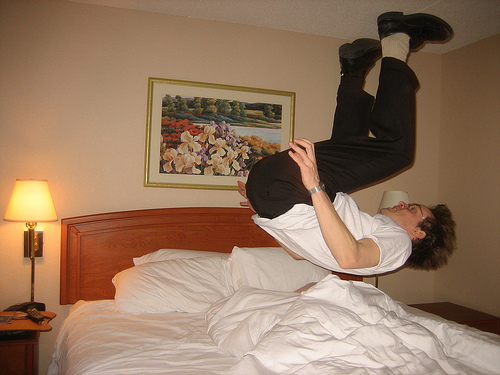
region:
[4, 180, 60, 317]
lamp on end table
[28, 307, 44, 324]
remote control on table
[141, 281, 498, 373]
white comforter on bed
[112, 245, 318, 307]
pillows laying on bed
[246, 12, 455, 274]
man jumping on bed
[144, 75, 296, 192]
picture hanging on wall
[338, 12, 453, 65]
black leather dress shoes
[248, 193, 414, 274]
white cotton tee shirt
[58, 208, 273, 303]
brown wood head board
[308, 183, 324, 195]
silver watch on wrist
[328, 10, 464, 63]
His shoes are black.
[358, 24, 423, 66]
His sock is tan.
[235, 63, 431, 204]
The pants are black.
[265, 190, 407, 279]
The shirt is white.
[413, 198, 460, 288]
His hair is brown.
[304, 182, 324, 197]
His watch is silver.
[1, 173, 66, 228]
The light is on.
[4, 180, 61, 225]
The lights is orange.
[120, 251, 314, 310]
The pillows are white.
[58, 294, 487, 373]
The comforter is white.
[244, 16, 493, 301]
Man flipping on a bed.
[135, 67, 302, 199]
Floral picture on the wall.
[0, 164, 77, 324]
Wall mounted light fixture.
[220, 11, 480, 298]
A man wearing a white shirt and black pants.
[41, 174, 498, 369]
An unmade bed.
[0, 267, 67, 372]
A cluttered nightstand.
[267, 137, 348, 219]
A silver watch.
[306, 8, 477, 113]
Black shoes and tan socks.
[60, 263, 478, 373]
White sheets and pillowcases.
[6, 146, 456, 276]
One light is on, the other is off.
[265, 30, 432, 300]
MAN JUMPING ON HOTEL BED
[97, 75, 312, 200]
PAINTING HANGING ON WALL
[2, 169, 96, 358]
ILLUMINATED LAMP BY BED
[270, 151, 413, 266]
WHITE SHIRT ON MAN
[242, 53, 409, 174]
BLACK LONG PANTS ON MAN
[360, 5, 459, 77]
BLACK DRESS SHOES ON MAN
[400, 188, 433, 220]
EYEGLASSES ON MAN'S FACE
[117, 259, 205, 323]
WHITE PILLOW ON BED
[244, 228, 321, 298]
WHITE PILLOW ON BED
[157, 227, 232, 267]
WHITE PILLOW ON BED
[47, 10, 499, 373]
Man doing a flip off a bed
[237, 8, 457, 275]
man upside down in the air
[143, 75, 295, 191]
Painting in a gold frame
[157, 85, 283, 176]
Painting of colorful flowers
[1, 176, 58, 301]
Hotel wall lamp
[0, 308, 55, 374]
Light brown night stand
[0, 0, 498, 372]
Man doing a flip in a hotel room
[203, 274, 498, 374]
White down comforter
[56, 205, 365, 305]
Light wood wall mounted headboard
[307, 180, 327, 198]
Silver watch